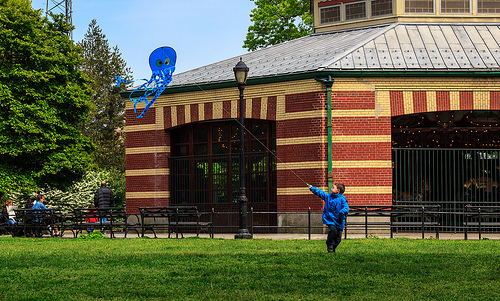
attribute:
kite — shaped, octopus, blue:
[110, 41, 182, 120]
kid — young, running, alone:
[303, 178, 351, 259]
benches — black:
[9, 206, 215, 238]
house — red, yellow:
[112, 1, 494, 237]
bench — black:
[8, 205, 60, 237]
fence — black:
[204, 208, 499, 244]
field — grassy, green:
[2, 237, 499, 301]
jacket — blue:
[307, 185, 354, 227]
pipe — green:
[324, 75, 334, 189]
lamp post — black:
[231, 53, 254, 242]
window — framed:
[313, 1, 344, 27]